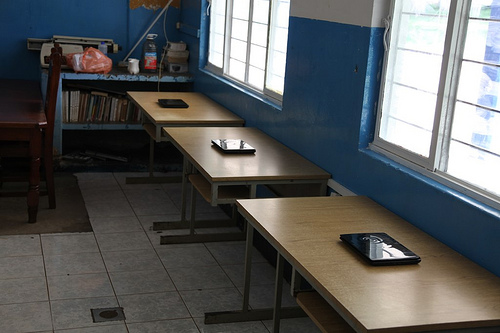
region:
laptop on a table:
[332, 225, 404, 279]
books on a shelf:
[63, 92, 123, 131]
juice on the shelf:
[135, 18, 169, 80]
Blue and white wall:
[290, 11, 385, 83]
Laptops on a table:
[132, 81, 381, 329]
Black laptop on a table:
[210, 137, 263, 172]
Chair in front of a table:
[23, 65, 71, 195]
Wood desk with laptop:
[239, 181, 443, 326]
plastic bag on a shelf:
[71, 40, 98, 75]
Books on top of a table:
[164, 27, 199, 81]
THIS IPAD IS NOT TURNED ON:
[341, 221, 436, 286]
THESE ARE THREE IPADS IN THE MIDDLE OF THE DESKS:
[150, 85, 433, 291]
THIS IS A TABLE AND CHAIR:
[0, 30, 71, 227]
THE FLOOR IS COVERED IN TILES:
[6, 165, 312, 330]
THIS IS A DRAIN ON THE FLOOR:
[90, 302, 138, 330]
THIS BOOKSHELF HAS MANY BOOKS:
[30, 50, 215, 180]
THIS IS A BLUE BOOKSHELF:
[42, 47, 187, 182]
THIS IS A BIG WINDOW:
[355, 0, 497, 225]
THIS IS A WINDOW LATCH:
[367, 5, 393, 70]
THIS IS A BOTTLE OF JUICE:
[140, 28, 165, 82]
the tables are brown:
[117, 82, 497, 332]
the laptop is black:
[336, 223, 421, 268]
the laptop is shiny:
[207, 134, 257, 156]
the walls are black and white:
[0, 2, 499, 278]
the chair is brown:
[0, 43, 72, 216]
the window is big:
[359, 0, 497, 217]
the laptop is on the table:
[233, 188, 498, 331]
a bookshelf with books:
[42, 62, 192, 180]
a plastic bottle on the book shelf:
[138, 29, 165, 77]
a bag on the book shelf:
[62, 44, 114, 76]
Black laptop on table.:
[336, 230, 421, 267]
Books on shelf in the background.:
[60, 83, 139, 125]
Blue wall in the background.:
[0, 0, 177, 73]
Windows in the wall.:
[365, 1, 497, 215]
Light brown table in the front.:
[209, 193, 496, 331]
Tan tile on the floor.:
[1, 172, 308, 332]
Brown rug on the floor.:
[0, 163, 99, 239]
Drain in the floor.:
[86, 303, 129, 322]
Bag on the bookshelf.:
[80, 45, 112, 75]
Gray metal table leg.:
[197, 222, 284, 327]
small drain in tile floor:
[91, 300, 125, 325]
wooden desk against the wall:
[154, 120, 313, 245]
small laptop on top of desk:
[330, 217, 422, 283]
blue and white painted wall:
[310, 3, 352, 53]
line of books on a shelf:
[54, 79, 128, 124]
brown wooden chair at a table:
[29, 45, 67, 214]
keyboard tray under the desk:
[182, 172, 217, 211]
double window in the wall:
[384, 11, 479, 178]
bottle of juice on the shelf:
[143, 34, 162, 74]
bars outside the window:
[453, 56, 490, 133]